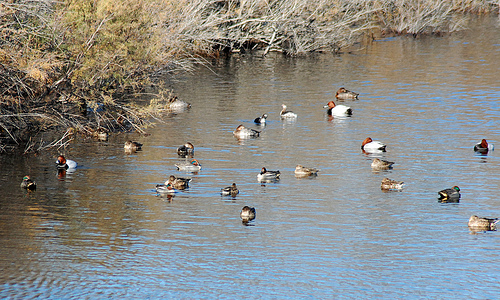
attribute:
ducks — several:
[14, 81, 497, 241]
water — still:
[3, 81, 500, 299]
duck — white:
[322, 100, 356, 121]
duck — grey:
[252, 163, 284, 184]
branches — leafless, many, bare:
[164, 5, 474, 47]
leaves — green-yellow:
[0, 0, 164, 123]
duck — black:
[434, 182, 466, 206]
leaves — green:
[43, 2, 174, 95]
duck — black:
[18, 172, 40, 195]